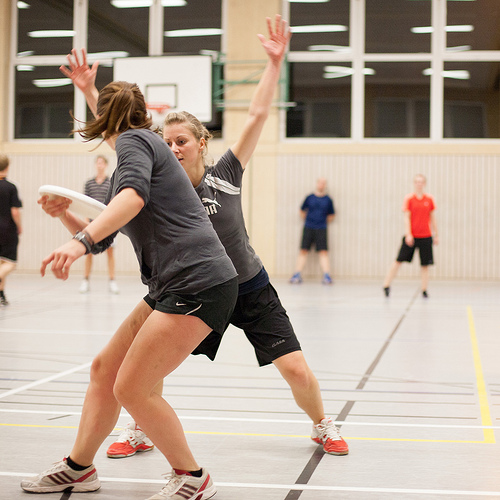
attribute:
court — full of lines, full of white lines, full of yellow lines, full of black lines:
[2, 268, 497, 498]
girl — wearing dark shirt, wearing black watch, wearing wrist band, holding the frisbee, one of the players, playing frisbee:
[18, 80, 240, 499]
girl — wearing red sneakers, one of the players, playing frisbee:
[57, 13, 352, 460]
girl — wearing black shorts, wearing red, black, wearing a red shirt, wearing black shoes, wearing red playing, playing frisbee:
[378, 172, 442, 299]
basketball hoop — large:
[112, 57, 213, 130]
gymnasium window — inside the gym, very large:
[285, 1, 355, 140]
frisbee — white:
[40, 185, 113, 222]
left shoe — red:
[308, 421, 348, 457]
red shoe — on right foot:
[102, 421, 159, 461]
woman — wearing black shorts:
[0, 156, 24, 306]